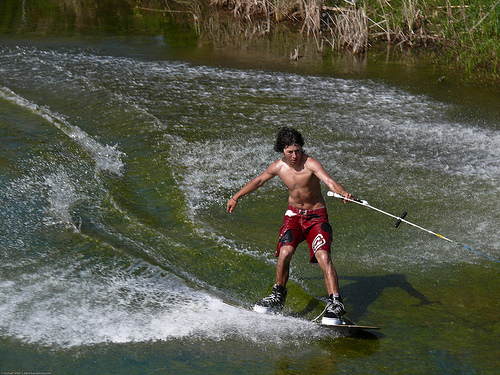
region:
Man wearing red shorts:
[261, 192, 363, 268]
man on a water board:
[255, 268, 382, 334]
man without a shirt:
[256, 155, 338, 228]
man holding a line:
[310, 176, 367, 219]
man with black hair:
[253, 120, 313, 176]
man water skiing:
[248, 145, 395, 352]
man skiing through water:
[229, 154, 380, 325]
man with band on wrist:
[228, 183, 264, 235]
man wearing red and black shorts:
[249, 204, 346, 269]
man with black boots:
[249, 266, 289, 314]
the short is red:
[253, 199, 355, 278]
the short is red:
[270, 195, 344, 277]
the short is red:
[258, 191, 344, 295]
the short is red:
[263, 194, 339, 261]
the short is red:
[266, 189, 366, 276]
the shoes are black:
[247, 275, 367, 355]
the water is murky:
[129, 188, 206, 288]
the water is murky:
[386, 278, 465, 361]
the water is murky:
[106, 309, 259, 374]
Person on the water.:
[188, 94, 485, 371]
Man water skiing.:
[228, 262, 360, 367]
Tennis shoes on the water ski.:
[212, 256, 455, 373]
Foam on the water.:
[33, 252, 208, 359]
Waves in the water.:
[133, 220, 296, 368]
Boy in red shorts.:
[212, 99, 405, 331]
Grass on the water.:
[196, 7, 447, 68]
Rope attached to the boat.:
[326, 146, 493, 291]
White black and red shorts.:
[261, 185, 365, 274]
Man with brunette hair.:
[196, 101, 485, 338]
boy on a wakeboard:
[240, 64, 382, 369]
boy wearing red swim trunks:
[272, 192, 337, 284]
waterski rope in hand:
[325, 175, 452, 256]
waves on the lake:
[180, 281, 290, 345]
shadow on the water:
[351, 252, 441, 319]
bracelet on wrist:
[223, 186, 246, 208]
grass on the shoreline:
[455, 20, 491, 76]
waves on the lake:
[46, 141, 117, 270]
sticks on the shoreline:
[296, 0, 406, 51]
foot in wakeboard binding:
[317, 288, 352, 338]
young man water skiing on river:
[230, 123, 345, 333]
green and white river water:
[39, 46, 97, 112]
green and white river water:
[25, 119, 102, 173]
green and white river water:
[2, 138, 82, 236]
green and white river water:
[56, 169, 121, 217]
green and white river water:
[39, 249, 97, 312]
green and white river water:
[105, 245, 194, 341]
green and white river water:
[351, 243, 397, 269]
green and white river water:
[139, 96, 237, 149]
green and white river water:
[332, 100, 409, 158]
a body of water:
[8, 28, 488, 373]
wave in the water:
[33, 43, 284, 309]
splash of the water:
[8, 118, 136, 243]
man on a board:
[230, 125, 378, 343]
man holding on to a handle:
[320, 180, 370, 216]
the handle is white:
[319, 179, 373, 225]